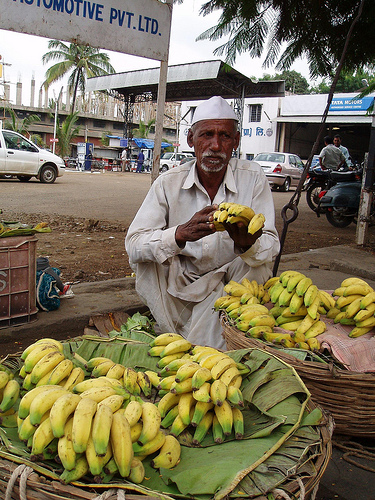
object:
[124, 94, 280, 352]
man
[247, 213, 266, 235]
bananas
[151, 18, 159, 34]
letter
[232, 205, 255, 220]
bananas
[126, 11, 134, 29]
letter